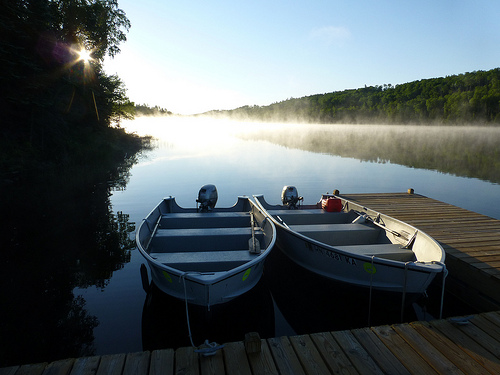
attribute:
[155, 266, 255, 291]
circles — yellow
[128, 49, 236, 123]
clouds — white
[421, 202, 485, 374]
dock — wood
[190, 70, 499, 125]
tree — large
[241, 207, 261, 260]
oar — silver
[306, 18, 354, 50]
clouds — white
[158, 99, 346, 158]
steam — white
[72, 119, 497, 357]
water — still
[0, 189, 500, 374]
dock — a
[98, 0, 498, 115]
sky — blue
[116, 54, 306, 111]
clouds — white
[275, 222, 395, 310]
boat — anchored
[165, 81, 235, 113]
clouds — white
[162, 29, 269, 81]
sky — blue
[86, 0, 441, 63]
sky — blue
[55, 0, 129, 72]
leaves — tree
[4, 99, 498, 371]
scene — a